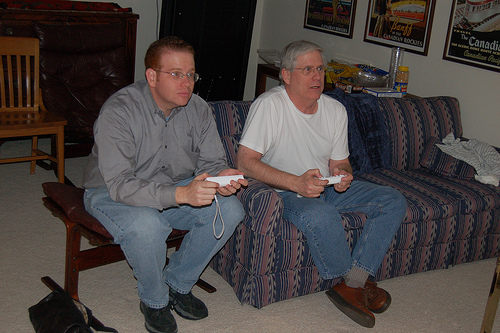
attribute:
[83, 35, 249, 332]
man — playing, sitting, younger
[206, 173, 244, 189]
controller — present, white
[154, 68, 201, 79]
glasses — silver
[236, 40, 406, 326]
man — playing, sitting, older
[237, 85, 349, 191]
shirt — present, white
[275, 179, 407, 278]
blue jeans — dark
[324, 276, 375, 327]
shoe — dressy, brown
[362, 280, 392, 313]
shoe — dressy, brown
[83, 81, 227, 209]
shirt — oxford, button up, gray, grey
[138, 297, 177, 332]
shoe — blue, black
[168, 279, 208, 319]
shoe — black, blue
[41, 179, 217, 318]
seat — brown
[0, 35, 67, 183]
chair — brown, wooden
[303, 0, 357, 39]
framed poster — hanging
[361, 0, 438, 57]
framed poster — hanging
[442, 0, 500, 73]
framed poster — hanging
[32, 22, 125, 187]
recliner — leather, brown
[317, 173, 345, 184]
controller — white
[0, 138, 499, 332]
carpet — white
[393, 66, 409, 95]
container — small, plastic